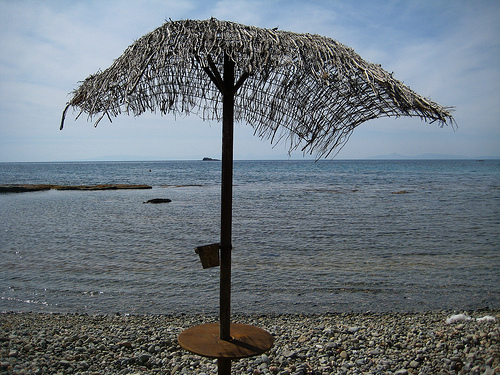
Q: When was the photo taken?
A: Daytime.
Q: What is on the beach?
A: Rocks.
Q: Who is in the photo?
A: Nobody.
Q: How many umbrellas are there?
A: One.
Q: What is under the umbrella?
A: A table.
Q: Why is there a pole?
A: To support the umbrella.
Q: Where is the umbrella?
A: On the pole.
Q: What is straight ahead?
A: The water.